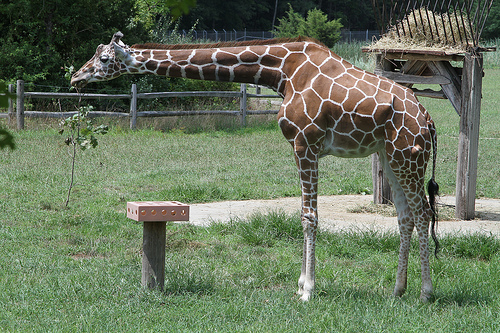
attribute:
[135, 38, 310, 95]
neck — long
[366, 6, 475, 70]
hay — tan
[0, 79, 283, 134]
fence — wooden, short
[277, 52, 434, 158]
body — strong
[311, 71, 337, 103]
spot — brown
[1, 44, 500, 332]
grass — green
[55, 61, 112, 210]
tree — small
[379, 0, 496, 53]
grid — metal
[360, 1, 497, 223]
feeder — wooden